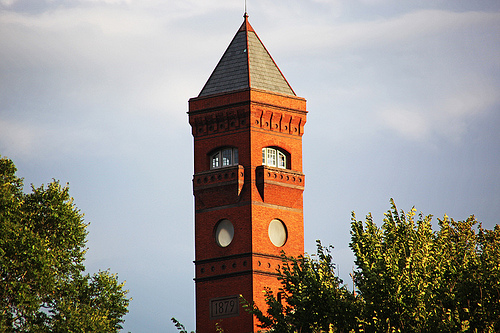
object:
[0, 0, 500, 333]
cloud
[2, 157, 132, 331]
tree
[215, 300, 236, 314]
number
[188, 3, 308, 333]
tower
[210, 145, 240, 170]
window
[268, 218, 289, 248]
circle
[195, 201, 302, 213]
line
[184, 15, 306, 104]
roof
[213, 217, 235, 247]
circle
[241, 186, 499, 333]
tree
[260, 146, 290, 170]
window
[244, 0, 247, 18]
rod